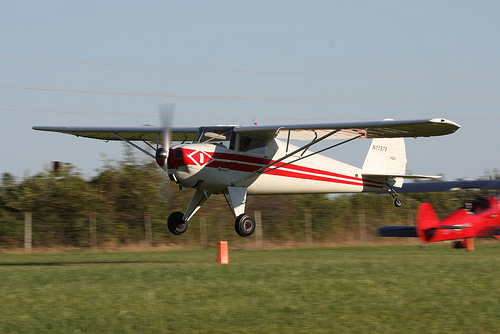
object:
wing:
[30, 113, 460, 142]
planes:
[29, 103, 462, 238]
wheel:
[166, 210, 191, 235]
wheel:
[234, 212, 257, 239]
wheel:
[394, 197, 405, 209]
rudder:
[357, 111, 410, 192]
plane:
[391, 170, 498, 267]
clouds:
[29, 22, 112, 86]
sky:
[1, 1, 498, 169]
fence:
[290, 212, 345, 237]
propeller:
[151, 99, 180, 203]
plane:
[26, 81, 462, 272]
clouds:
[238, 65, 314, 112]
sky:
[15, 15, 472, 126]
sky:
[13, 4, 494, 106]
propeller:
[157, 99, 176, 199]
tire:
[231, 211, 256, 240]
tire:
[164, 208, 190, 237]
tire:
[392, 195, 407, 211]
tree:
[0, 161, 113, 235]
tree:
[91, 161, 169, 220]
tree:
[249, 192, 332, 213]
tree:
[330, 193, 387, 211]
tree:
[420, 189, 458, 218]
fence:
[258, 206, 390, 246]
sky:
[2, 0, 497, 207]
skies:
[65, 17, 465, 89]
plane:
[30, 108, 467, 264]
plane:
[400, 182, 497, 251]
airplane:
[27, 116, 463, 236]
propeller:
[133, 105, 197, 203]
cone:
[205, 234, 242, 279]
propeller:
[100, 105, 221, 213]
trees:
[8, 171, 498, 257]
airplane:
[28, 47, 496, 241]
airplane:
[33, 97, 457, 234]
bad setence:
[191, 51, 412, 87]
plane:
[380, 194, 497, 256]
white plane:
[27, 116, 463, 235]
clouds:
[1, 58, 72, 122]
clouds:
[111, 32, 236, 93]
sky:
[2, 0, 497, 120]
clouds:
[111, 37, 207, 88]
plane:
[26, 104, 463, 236]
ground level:
[1, 249, 498, 331]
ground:
[1, 250, 499, 330]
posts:
[23, 214, 97, 252]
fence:
[0, 207, 499, 250]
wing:
[28, 107, 165, 176]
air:
[1, 0, 498, 113]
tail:
[403, 108, 452, 238]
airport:
[9, 88, 493, 334]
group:
[44, 130, 496, 177]